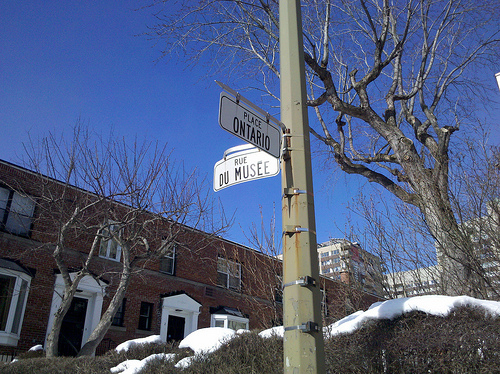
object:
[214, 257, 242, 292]
window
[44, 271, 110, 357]
door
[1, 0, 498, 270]
skies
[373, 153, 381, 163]
ground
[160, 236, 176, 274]
window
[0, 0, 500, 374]
picture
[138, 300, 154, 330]
window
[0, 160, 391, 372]
building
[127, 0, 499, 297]
tree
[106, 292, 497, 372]
snow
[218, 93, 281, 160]
sign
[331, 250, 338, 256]
window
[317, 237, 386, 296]
building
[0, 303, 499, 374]
grass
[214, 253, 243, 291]
window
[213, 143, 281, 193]
sign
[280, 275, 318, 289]
metallic braces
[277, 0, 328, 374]
pole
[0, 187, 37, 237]
window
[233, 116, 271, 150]
lettering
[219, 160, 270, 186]
lettering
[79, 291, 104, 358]
frame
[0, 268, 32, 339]
window